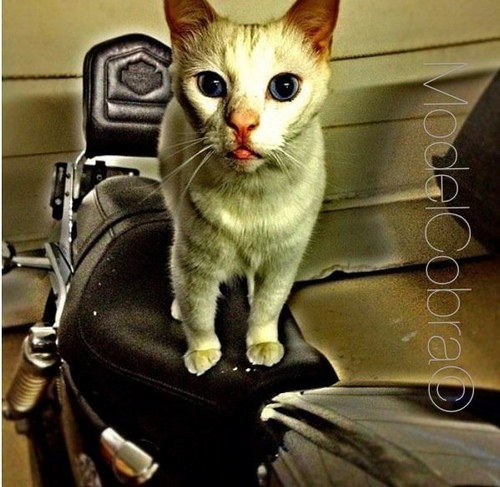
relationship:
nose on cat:
[221, 97, 271, 134] [140, 2, 350, 378]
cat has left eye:
[140, 2, 350, 378] [259, 68, 311, 108]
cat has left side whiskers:
[140, 2, 350, 378] [265, 140, 362, 209]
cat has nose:
[140, 2, 350, 378] [221, 97, 271, 134]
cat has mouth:
[140, 2, 350, 378] [217, 144, 265, 167]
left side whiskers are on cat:
[265, 140, 362, 209] [140, 2, 350, 378]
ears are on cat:
[156, 1, 357, 61] [140, 2, 350, 378]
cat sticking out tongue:
[140, 2, 350, 378] [228, 139, 256, 165]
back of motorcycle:
[57, 25, 198, 150] [9, 28, 497, 486]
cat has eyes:
[140, 2, 350, 378] [193, 64, 309, 110]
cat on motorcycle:
[140, 2, 350, 378] [9, 28, 497, 486]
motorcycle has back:
[9, 28, 497, 486] [57, 25, 198, 150]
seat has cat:
[61, 167, 350, 483] [140, 2, 350, 378]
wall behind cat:
[6, 5, 500, 303] [140, 2, 350, 378]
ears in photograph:
[156, 1, 357, 61] [0, 0, 479, 471]